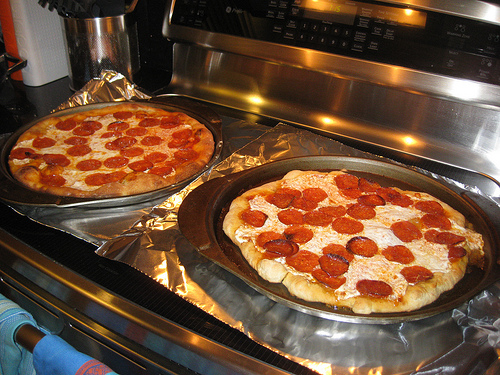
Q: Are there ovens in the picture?
A: Yes, there is an oven.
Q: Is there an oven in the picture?
A: Yes, there is an oven.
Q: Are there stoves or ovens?
A: Yes, there is an oven.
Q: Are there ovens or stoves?
A: Yes, there is an oven.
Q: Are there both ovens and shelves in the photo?
A: No, there is an oven but no shelves.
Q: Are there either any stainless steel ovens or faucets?
A: Yes, there is a stainless steel oven.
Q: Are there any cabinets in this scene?
A: No, there are no cabinets.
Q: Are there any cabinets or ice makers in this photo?
A: No, there are no cabinets or ice makers.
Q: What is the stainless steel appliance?
A: The appliance is an oven.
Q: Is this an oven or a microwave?
A: This is an oven.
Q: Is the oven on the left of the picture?
A: Yes, the oven is on the left of the image.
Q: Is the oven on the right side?
A: No, the oven is on the left of the image.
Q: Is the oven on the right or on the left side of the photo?
A: The oven is on the left of the image.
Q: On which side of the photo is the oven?
A: The oven is on the left of the image.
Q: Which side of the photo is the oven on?
A: The oven is on the left of the image.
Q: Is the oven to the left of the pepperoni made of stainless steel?
A: Yes, the oven is made of stainless steel.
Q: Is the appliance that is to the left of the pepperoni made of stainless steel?
A: Yes, the oven is made of stainless steel.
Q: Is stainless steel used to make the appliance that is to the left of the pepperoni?
A: Yes, the oven is made of stainless steel.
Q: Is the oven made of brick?
A: No, the oven is made of stainless steel.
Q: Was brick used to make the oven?
A: No, the oven is made of stainless steel.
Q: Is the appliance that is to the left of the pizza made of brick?
A: No, the oven is made of stainless steel.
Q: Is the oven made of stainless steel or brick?
A: The oven is made of stainless steel.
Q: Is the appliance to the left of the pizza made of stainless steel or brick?
A: The oven is made of stainless steel.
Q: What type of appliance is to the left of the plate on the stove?
A: The appliance is an oven.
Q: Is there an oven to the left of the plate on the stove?
A: Yes, there is an oven to the left of the plate.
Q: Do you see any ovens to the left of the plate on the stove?
A: Yes, there is an oven to the left of the plate.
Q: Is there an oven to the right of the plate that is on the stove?
A: No, the oven is to the left of the plate.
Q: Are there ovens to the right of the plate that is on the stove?
A: No, the oven is to the left of the plate.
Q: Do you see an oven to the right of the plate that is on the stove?
A: No, the oven is to the left of the plate.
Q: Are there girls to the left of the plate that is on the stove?
A: No, there is an oven to the left of the plate.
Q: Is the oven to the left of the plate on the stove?
A: Yes, the oven is to the left of the plate.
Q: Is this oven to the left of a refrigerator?
A: No, the oven is to the left of the plate.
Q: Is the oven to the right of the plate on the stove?
A: No, the oven is to the left of the plate.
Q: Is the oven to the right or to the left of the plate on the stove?
A: The oven is to the left of the plate.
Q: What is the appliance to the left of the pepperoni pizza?
A: The appliance is an oven.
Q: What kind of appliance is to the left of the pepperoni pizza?
A: The appliance is an oven.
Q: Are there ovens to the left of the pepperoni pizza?
A: Yes, there is an oven to the left of the pizza.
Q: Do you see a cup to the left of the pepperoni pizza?
A: No, there is an oven to the left of the pizza.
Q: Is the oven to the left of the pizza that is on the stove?
A: Yes, the oven is to the left of the pizza.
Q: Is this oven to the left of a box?
A: No, the oven is to the left of the pizza.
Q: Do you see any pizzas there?
A: Yes, there is a pizza.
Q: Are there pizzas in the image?
A: Yes, there is a pizza.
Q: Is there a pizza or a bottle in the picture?
A: Yes, there is a pizza.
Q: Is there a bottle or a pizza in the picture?
A: Yes, there is a pizza.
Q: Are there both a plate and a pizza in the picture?
A: Yes, there are both a pizza and a plate.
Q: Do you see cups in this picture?
A: No, there are no cups.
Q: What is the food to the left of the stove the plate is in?
A: The food is a pizza.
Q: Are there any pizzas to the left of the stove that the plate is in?
A: Yes, there is a pizza to the left of the stove.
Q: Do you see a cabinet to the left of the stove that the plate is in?
A: No, there is a pizza to the left of the stove.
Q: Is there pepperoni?
A: Yes, there is pepperoni.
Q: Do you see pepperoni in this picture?
A: Yes, there is pepperoni.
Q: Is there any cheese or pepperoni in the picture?
A: Yes, there is pepperoni.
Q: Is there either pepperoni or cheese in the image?
A: Yes, there is pepperoni.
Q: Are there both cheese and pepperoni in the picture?
A: Yes, there are both pepperoni and cheese.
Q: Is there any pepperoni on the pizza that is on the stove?
A: Yes, there is pepperoni on the pizza.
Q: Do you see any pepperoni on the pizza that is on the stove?
A: Yes, there is pepperoni on the pizza.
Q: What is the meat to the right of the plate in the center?
A: The meat is pepperoni.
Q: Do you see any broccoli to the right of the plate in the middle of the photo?
A: No, there is pepperoni to the right of the plate.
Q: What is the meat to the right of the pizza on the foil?
A: The meat is pepperoni.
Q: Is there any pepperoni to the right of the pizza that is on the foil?
A: Yes, there is pepperoni to the right of the pizza.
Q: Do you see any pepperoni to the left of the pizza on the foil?
A: No, the pepperoni is to the right of the pizza.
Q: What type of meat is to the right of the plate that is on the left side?
A: The meat is pepperoni.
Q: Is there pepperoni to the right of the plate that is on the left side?
A: Yes, there is pepperoni to the right of the plate.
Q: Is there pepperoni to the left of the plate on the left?
A: No, the pepperoni is to the right of the plate.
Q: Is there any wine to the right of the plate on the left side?
A: No, there is pepperoni to the right of the plate.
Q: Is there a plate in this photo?
A: Yes, there is a plate.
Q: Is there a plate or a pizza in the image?
A: Yes, there is a plate.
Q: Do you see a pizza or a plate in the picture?
A: Yes, there is a plate.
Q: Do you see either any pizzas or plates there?
A: Yes, there is a plate.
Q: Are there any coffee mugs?
A: No, there are no coffee mugs.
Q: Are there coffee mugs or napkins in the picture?
A: No, there are no coffee mugs or napkins.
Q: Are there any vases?
A: No, there are no vases.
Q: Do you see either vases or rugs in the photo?
A: No, there are no vases or rugs.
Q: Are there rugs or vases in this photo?
A: No, there are no vases or rugs.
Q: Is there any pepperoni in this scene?
A: Yes, there is pepperoni.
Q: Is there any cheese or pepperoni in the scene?
A: Yes, there is pepperoni.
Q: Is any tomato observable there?
A: No, there are no tomatoes.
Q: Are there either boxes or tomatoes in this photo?
A: No, there are no tomatoes or boxes.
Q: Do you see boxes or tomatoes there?
A: No, there are no tomatoes or boxes.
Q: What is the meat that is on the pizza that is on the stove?
A: The meat is pepperoni.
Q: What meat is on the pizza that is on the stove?
A: The meat is pepperoni.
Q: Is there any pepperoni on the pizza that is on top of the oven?
A: Yes, there is pepperoni on the pizza.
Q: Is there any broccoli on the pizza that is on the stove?
A: No, there is pepperoni on the pizza.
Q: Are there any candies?
A: No, there are no candies.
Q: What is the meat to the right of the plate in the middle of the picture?
A: The meat is pepperoni.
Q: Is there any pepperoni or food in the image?
A: Yes, there is pepperoni.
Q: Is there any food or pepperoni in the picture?
A: Yes, there is pepperoni.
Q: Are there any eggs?
A: No, there are no eggs.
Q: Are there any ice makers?
A: No, there are no ice makers.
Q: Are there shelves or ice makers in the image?
A: No, there are no ice makers or shelves.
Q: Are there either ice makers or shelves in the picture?
A: No, there are no ice makers or shelves.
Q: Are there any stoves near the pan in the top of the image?
A: Yes, there is a stove near the pan.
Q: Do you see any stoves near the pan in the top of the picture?
A: Yes, there is a stove near the pan.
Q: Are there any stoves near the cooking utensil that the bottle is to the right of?
A: Yes, there is a stove near the pan.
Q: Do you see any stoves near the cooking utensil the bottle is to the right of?
A: Yes, there is a stove near the pan.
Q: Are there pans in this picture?
A: Yes, there is a pan.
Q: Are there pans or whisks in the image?
A: Yes, there is a pan.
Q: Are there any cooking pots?
A: No, there are no cooking pots.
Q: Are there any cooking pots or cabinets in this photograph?
A: No, there are no cooking pots or cabinets.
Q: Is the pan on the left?
A: Yes, the pan is on the left of the image.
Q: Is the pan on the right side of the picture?
A: No, the pan is on the left of the image.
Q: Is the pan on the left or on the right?
A: The pan is on the left of the image.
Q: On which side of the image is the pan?
A: The pan is on the left of the image.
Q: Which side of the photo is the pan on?
A: The pan is on the left of the image.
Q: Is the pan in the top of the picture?
A: Yes, the pan is in the top of the image.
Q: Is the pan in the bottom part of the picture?
A: No, the pan is in the top of the image.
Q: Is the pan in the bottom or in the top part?
A: The pan is in the top of the image.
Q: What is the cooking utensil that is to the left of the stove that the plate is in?
A: The cooking utensil is a pan.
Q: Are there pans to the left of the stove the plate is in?
A: Yes, there is a pan to the left of the stove.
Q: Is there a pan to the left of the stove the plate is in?
A: Yes, there is a pan to the left of the stove.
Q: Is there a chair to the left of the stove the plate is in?
A: No, there is a pan to the left of the stove.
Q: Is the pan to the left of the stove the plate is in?
A: Yes, the pan is to the left of the stove.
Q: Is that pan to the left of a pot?
A: No, the pan is to the left of the stove.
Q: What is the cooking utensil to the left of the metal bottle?
A: The cooking utensil is a pan.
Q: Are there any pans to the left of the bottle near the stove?
A: Yes, there is a pan to the left of the bottle.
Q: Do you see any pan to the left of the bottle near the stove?
A: Yes, there is a pan to the left of the bottle.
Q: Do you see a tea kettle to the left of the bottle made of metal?
A: No, there is a pan to the left of the bottle.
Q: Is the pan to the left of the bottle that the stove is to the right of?
A: Yes, the pan is to the left of the bottle.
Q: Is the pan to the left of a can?
A: No, the pan is to the left of the bottle.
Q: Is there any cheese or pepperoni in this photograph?
A: Yes, there is pepperoni.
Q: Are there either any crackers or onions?
A: No, there are no onions or crackers.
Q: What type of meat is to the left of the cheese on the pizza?
A: The meat is pepperoni.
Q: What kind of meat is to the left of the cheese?
A: The meat is pepperoni.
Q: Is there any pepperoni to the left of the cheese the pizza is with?
A: Yes, there is pepperoni to the left of the cheese.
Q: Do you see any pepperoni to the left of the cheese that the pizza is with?
A: Yes, there is pepperoni to the left of the cheese.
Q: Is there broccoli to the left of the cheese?
A: No, there is pepperoni to the left of the cheese.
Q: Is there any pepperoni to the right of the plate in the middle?
A: Yes, there is pepperoni to the right of the plate.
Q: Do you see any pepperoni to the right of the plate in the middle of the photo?
A: Yes, there is pepperoni to the right of the plate.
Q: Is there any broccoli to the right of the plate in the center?
A: No, there is pepperoni to the right of the plate.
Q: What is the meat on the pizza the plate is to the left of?
A: The meat is pepperoni.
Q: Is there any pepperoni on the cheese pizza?
A: Yes, there is pepperoni on the pizza.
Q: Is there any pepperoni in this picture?
A: Yes, there is pepperoni.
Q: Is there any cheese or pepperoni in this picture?
A: Yes, there is pepperoni.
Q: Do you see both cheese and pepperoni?
A: Yes, there are both pepperoni and cheese.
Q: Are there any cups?
A: No, there are no cups.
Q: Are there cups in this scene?
A: No, there are no cups.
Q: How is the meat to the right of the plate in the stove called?
A: The meat is pepperoni.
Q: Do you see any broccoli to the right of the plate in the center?
A: No, there is pepperoni to the right of the plate.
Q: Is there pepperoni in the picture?
A: Yes, there is pepperoni.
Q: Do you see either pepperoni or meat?
A: Yes, there is pepperoni.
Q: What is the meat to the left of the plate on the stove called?
A: The meat is pepperoni.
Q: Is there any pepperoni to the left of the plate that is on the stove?
A: Yes, there is pepperoni to the left of the plate.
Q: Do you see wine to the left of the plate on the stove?
A: No, there is pepperoni to the left of the plate.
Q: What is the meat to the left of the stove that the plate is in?
A: The meat is pepperoni.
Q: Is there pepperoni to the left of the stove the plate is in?
A: Yes, there is pepperoni to the left of the stove.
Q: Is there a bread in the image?
A: No, there is no breads.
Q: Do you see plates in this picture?
A: Yes, there is a plate.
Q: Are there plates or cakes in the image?
A: Yes, there is a plate.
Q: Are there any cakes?
A: No, there are no cakes.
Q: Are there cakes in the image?
A: No, there are no cakes.